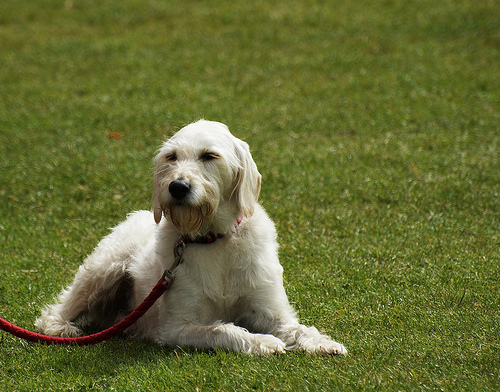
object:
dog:
[33, 119, 349, 357]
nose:
[168, 178, 192, 198]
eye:
[198, 151, 220, 164]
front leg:
[158, 320, 262, 352]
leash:
[0, 205, 251, 348]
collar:
[177, 209, 244, 244]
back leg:
[60, 267, 111, 323]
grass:
[0, 0, 499, 392]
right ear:
[153, 172, 163, 226]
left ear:
[233, 139, 263, 220]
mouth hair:
[155, 198, 217, 229]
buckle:
[162, 235, 188, 285]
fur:
[30, 117, 350, 358]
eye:
[162, 149, 178, 162]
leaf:
[105, 131, 123, 143]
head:
[146, 117, 264, 238]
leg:
[235, 296, 315, 342]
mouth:
[160, 180, 207, 217]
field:
[0, 0, 498, 392]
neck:
[162, 204, 249, 245]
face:
[156, 145, 225, 192]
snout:
[168, 174, 193, 201]